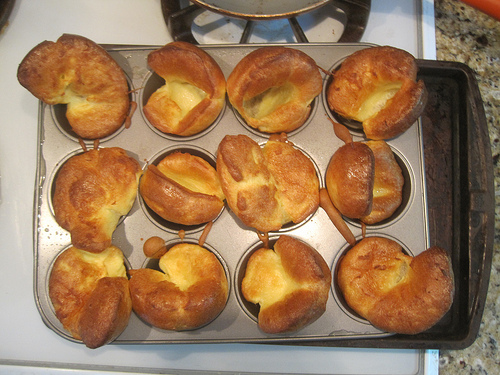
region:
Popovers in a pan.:
[32, 40, 462, 311]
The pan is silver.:
[41, 56, 418, 330]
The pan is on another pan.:
[22, 38, 466, 373]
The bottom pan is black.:
[431, 81, 499, 346]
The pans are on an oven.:
[1, 45, 497, 372]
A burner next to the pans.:
[151, 1, 380, 48]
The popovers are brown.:
[13, 50, 436, 322]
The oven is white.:
[6, 317, 384, 374]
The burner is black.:
[169, 5, 385, 42]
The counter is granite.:
[437, 8, 499, 73]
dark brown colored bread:
[13, 36, 123, 136]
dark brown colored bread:
[141, 38, 219, 138]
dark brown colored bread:
[224, 45, 312, 135]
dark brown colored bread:
[324, 44, 426, 138]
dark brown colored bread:
[48, 147, 141, 252]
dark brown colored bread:
[137, 147, 218, 229]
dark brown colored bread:
[206, 133, 323, 233]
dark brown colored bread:
[322, 141, 408, 230]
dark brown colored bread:
[48, 245, 131, 352]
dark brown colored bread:
[130, 239, 229, 337]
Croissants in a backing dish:
[21, 39, 486, 348]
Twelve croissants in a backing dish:
[28, 41, 463, 340]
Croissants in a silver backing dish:
[17, 26, 447, 355]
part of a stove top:
[142, 0, 381, 32]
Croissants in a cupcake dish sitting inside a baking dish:
[6, 24, 487, 351]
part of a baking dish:
[426, 52, 499, 372]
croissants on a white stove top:
[3, 7, 236, 372]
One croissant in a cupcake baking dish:
[40, 144, 140, 233]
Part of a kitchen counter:
[445, 13, 497, 160]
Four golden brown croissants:
[30, 38, 416, 137]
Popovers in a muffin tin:
[14, 28, 456, 353]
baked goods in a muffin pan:
[12, 33, 448, 350]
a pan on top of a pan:
[12, 31, 494, 368]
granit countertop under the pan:
[440, 30, 497, 374]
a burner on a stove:
[155, 21, 387, 48]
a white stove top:
[5, 93, 37, 362]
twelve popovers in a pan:
[12, 35, 460, 346]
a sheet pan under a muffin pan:
[406, 45, 493, 360]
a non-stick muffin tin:
[17, 38, 445, 345]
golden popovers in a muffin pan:
[16, 32, 457, 352]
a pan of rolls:
[45, 37, 461, 347]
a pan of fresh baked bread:
[14, 37, 453, 334]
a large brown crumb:
[133, 232, 171, 259]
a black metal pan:
[431, 63, 498, 343]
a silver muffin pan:
[123, 117, 150, 154]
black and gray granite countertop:
[440, 350, 496, 373]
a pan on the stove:
[182, 0, 351, 19]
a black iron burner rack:
[169, 17, 351, 41]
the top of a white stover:
[31, 3, 161, 34]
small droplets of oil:
[36, 222, 66, 242]